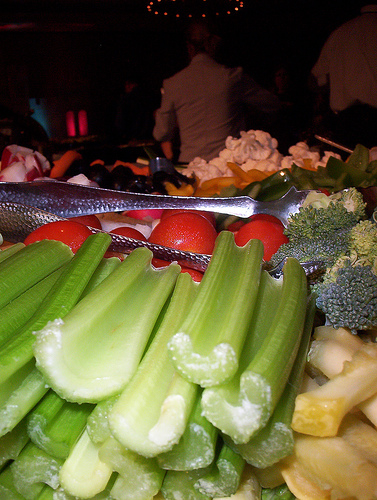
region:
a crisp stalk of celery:
[256, 257, 300, 411]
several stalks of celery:
[0, 240, 296, 492]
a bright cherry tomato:
[147, 208, 212, 251]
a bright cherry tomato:
[232, 219, 289, 258]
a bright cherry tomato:
[24, 219, 88, 254]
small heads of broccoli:
[271, 197, 376, 324]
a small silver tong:
[0, 174, 345, 291]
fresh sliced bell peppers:
[289, 145, 373, 196]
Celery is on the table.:
[3, 294, 290, 457]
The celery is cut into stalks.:
[167, 230, 262, 388]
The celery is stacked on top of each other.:
[29, 299, 282, 469]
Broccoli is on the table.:
[290, 204, 356, 252]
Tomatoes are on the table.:
[160, 216, 207, 244]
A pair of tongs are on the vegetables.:
[0, 178, 246, 214]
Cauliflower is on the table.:
[230, 135, 269, 160]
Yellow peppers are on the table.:
[229, 171, 254, 182]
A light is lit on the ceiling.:
[146, 0, 244, 19]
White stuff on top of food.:
[298, 373, 346, 453]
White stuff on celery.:
[214, 394, 275, 440]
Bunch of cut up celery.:
[28, 229, 261, 442]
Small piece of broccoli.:
[309, 260, 369, 324]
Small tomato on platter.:
[156, 210, 217, 247]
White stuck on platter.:
[210, 106, 294, 176]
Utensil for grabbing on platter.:
[1, 163, 304, 267]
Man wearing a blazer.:
[163, 9, 284, 169]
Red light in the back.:
[43, 106, 91, 139]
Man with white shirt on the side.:
[319, 38, 368, 83]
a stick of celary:
[174, 232, 262, 382]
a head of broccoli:
[314, 268, 375, 325]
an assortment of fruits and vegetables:
[0, 141, 375, 495]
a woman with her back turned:
[160, 27, 239, 159]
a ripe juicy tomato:
[146, 213, 219, 259]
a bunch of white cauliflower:
[196, 129, 316, 173]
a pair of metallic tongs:
[0, 178, 329, 279]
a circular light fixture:
[146, 0, 247, 16]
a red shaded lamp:
[65, 103, 88, 136]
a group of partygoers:
[103, 1, 375, 150]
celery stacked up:
[27, 135, 366, 478]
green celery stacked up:
[27, 205, 371, 468]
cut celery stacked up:
[14, 246, 376, 485]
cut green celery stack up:
[49, 214, 362, 456]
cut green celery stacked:
[87, 263, 291, 498]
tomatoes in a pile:
[46, 154, 342, 404]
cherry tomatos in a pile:
[41, 167, 332, 347]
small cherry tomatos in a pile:
[68, 173, 360, 323]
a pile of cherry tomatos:
[73, 176, 373, 407]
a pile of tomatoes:
[55, 184, 318, 285]